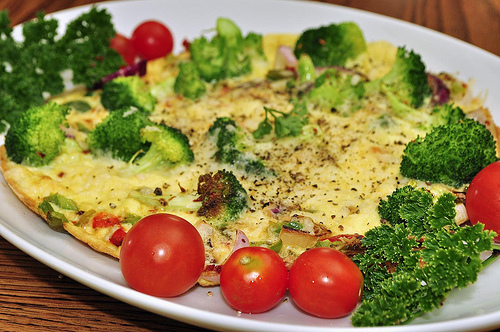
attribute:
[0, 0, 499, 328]
table — wood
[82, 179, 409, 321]
tomatoes — three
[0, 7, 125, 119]
parsley — Fresh green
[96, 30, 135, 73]
tomato — cherry, Bright red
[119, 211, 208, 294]
tomato — chunk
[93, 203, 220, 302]
tomato —  large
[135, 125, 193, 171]
broccoli — pieces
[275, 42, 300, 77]
onions — chopped 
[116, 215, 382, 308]
cherry tomato —  cherry 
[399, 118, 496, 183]
broccoli —  pieces 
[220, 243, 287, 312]
tomato — middle 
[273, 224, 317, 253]
onion — Bit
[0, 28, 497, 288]
egg — tasty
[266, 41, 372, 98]
ham — purple , pieces 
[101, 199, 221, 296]
tomato — small ,  middle,  bottom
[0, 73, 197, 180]
broccoli — Bright green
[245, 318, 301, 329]
plate — white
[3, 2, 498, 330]
plate — white